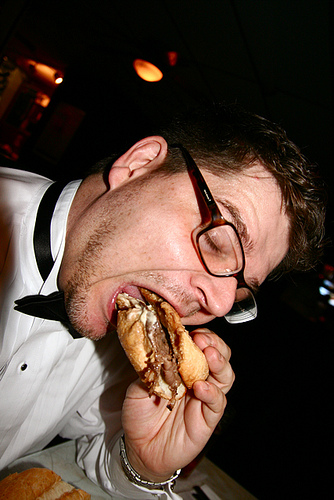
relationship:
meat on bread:
[137, 286, 185, 389] [113, 286, 210, 414]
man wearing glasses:
[90, 116, 275, 394] [173, 155, 274, 349]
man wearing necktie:
[90, 116, 275, 394] [32, 180, 68, 334]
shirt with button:
[11, 150, 180, 496] [11, 349, 55, 378]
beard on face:
[82, 209, 118, 336] [90, 116, 275, 394]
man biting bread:
[90, 116, 275, 394] [113, 286, 210, 414]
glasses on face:
[173, 155, 274, 349] [90, 123, 287, 356]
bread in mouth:
[113, 286, 210, 414] [97, 262, 202, 358]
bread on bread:
[144, 274, 227, 390] [113, 286, 210, 414]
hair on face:
[177, 105, 315, 259] [90, 123, 287, 356]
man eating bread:
[90, 116, 275, 394] [113, 286, 210, 414]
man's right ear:
[76, 121, 277, 354] [84, 118, 182, 184]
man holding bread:
[90, 116, 275, 394] [113, 286, 210, 414]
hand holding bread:
[119, 325, 236, 481] [113, 286, 210, 414]